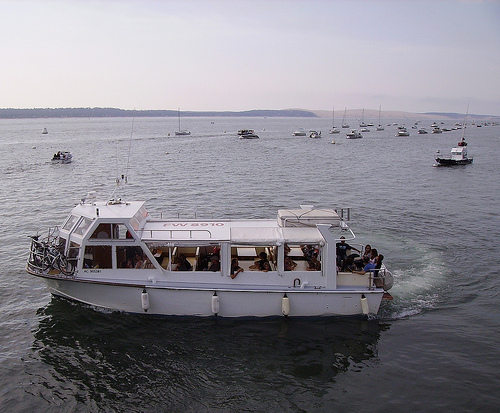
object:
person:
[230, 254, 244, 279]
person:
[254, 250, 271, 273]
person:
[354, 243, 373, 272]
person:
[130, 252, 144, 269]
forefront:
[0, 212, 488, 410]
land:
[2, 108, 329, 120]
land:
[418, 109, 499, 123]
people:
[335, 235, 359, 271]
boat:
[235, 119, 265, 156]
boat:
[346, 129, 363, 139]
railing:
[148, 219, 236, 250]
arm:
[229, 267, 242, 279]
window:
[229, 245, 276, 270]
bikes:
[23, 233, 76, 277]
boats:
[396, 129, 410, 137]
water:
[0, 117, 499, 413]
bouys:
[134, 284, 376, 320]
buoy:
[278, 295, 290, 316]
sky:
[0, 2, 497, 119]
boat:
[346, 130, 364, 139]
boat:
[417, 129, 429, 135]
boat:
[329, 103, 341, 134]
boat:
[288, 125, 309, 141]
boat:
[170, 108, 192, 138]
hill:
[314, 110, 418, 122]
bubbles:
[385, 252, 441, 298]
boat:
[24, 170, 399, 318]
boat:
[431, 103, 474, 166]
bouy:
[51, 148, 75, 166]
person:
[359, 255, 385, 280]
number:
[160, 219, 223, 228]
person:
[358, 249, 378, 276]